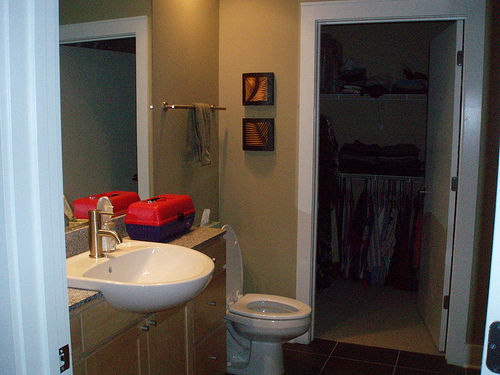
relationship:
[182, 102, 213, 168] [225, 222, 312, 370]
towel behind toilet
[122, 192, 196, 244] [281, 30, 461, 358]
carryall on counter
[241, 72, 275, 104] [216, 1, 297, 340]
pictures decorates wall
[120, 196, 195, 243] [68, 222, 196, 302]
carryall next to sink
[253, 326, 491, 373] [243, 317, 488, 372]
tiles on floor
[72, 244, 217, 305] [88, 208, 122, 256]
sink has fixtures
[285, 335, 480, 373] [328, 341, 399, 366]
floor set with tile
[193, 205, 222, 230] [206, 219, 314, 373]
tissues sits on top of toilet tank